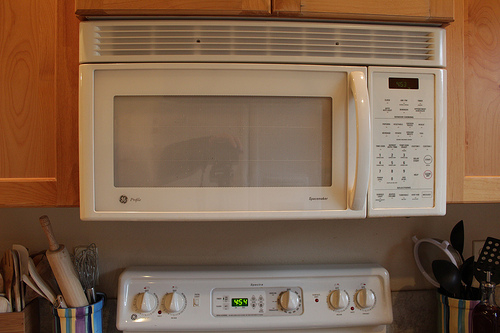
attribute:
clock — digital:
[389, 78, 420, 89]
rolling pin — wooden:
[37, 214, 88, 307]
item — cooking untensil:
[428, 258, 461, 299]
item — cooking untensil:
[480, 235, 500, 288]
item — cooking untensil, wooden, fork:
[1, 249, 15, 312]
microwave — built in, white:
[77, 16, 448, 222]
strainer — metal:
[410, 233, 463, 289]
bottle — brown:
[470, 282, 499, 332]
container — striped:
[52, 290, 104, 332]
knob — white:
[279, 288, 299, 311]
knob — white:
[328, 290, 348, 309]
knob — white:
[163, 291, 185, 313]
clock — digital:
[230, 296, 250, 307]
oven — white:
[114, 266, 394, 332]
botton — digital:
[423, 153, 435, 165]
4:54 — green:
[234, 297, 247, 305]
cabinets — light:
[1, 2, 499, 209]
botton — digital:
[424, 168, 434, 179]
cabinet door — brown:
[2, 2, 79, 208]